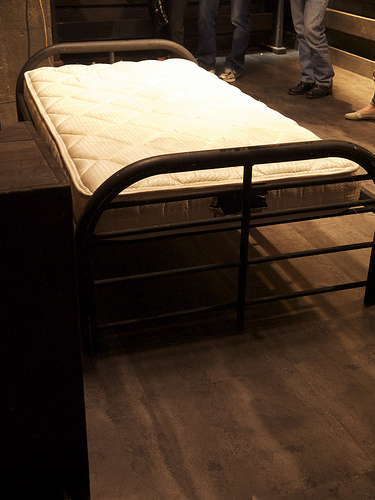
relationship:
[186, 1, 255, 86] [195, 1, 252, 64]
person wearing jeans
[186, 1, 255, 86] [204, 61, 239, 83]
person wearing tennis shoes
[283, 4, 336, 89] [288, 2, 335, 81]
person wearing jeans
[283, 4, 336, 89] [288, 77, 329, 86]
person wearing black boots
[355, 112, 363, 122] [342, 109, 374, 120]
slip on shoe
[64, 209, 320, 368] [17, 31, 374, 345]
shadow of bed frame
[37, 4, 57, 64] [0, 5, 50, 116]
cord hanging down wall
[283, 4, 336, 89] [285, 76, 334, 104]
man wearing shoes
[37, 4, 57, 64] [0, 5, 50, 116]
cord running down wall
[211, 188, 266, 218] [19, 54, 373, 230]
tag on mattress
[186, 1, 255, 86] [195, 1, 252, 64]
legs in blue jeans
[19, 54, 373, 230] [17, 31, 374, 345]
mattress on bed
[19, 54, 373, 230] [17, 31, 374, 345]
mattress on bed frame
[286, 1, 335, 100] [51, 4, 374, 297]
person standing around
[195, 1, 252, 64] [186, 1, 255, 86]
legs of a person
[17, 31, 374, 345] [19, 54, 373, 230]
bed frame of bed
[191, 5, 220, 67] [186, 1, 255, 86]
leg of a person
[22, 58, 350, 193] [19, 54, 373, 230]
top of mattress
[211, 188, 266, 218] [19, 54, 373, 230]
label on mattress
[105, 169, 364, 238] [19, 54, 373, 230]
front of mattress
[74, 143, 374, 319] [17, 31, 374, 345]
railing of bed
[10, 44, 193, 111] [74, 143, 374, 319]
part of railing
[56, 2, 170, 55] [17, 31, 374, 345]
shelf behind bed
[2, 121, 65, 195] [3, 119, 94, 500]
top of dresser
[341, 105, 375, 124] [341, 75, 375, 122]
foot of woman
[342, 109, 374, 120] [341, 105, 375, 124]
shoe on foot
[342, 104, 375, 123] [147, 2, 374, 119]
foot of legs